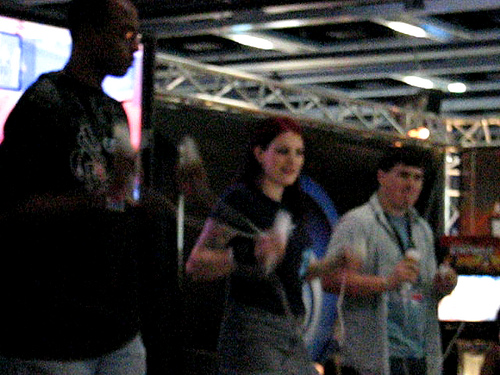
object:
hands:
[387, 259, 423, 290]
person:
[0, 0, 151, 375]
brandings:
[70, 103, 160, 213]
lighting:
[388, 20, 427, 38]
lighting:
[231, 34, 274, 50]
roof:
[0, 0, 499, 119]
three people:
[0, 0, 458, 375]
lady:
[186, 116, 358, 375]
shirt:
[327, 193, 444, 375]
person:
[324, 145, 458, 375]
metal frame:
[151, 0, 498, 151]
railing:
[147, 55, 500, 152]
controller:
[397, 245, 425, 297]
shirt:
[205, 182, 314, 319]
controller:
[254, 206, 299, 278]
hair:
[250, 116, 301, 150]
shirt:
[0, 71, 147, 360]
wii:
[94, 114, 151, 208]